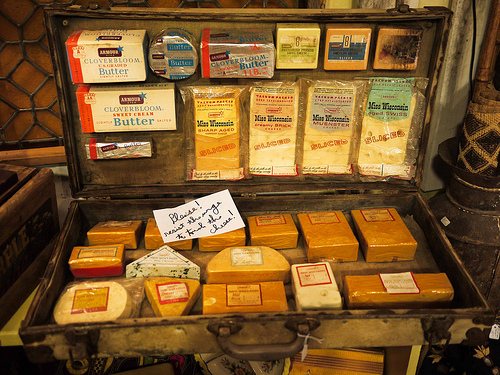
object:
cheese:
[180, 85, 245, 181]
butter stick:
[76, 83, 178, 133]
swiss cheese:
[248, 85, 298, 178]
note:
[152, 188, 246, 243]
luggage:
[20, 0, 493, 364]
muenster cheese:
[301, 86, 357, 175]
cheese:
[125, 244, 201, 281]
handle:
[217, 324, 310, 359]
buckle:
[421, 315, 455, 352]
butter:
[64, 29, 149, 83]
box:
[65, 29, 149, 84]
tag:
[297, 332, 325, 362]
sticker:
[301, 166, 326, 173]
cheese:
[291, 261, 343, 312]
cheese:
[53, 281, 132, 325]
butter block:
[148, 28, 200, 80]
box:
[1, 164, 61, 324]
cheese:
[206, 246, 291, 284]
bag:
[356, 77, 430, 183]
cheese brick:
[343, 272, 454, 308]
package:
[84, 141, 153, 160]